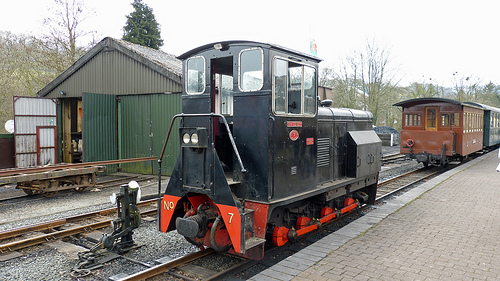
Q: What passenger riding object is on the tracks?
A: Train.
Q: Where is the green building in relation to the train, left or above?
A: Left.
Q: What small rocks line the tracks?
A: Gravel.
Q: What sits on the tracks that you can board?
A: Train.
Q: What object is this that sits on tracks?
A: Train.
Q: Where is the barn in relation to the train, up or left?
A: Left.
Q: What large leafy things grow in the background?
A: Trees.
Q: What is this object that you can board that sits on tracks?
A: Train.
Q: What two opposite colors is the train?
A: Orange and black.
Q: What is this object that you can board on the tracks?
A: Train.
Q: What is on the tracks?
A: Trains.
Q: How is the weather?
A: Clear.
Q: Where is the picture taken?
A: A station.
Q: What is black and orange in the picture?
A: A caboose.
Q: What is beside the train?
A: Green building.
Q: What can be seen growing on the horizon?
A: Trees.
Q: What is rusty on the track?
A: The rails.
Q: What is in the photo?
A: Front of train.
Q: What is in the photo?
A: The hitch.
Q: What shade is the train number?
A: Yellow.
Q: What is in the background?
A: Train cargo.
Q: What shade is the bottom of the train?
A: Red.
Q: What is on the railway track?
A: The train.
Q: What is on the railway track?
A: The train.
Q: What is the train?
A: Orange and black.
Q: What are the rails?
A: Rusted.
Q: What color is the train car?
A: Black.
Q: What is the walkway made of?
A: Bricks.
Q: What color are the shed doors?
A: Green.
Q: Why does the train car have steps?
A: So people can climb in.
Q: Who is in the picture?
A: Nobody.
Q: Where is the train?
A: On the tracks.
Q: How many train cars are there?
A: Three.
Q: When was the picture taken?
A: Daytime.